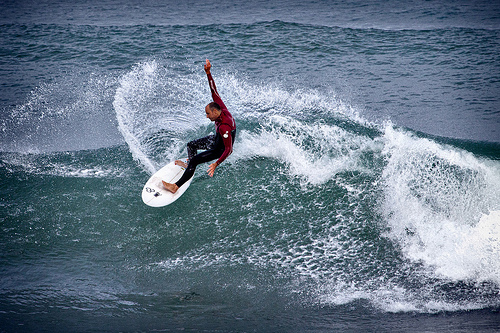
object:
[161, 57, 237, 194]
man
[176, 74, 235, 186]
wet suit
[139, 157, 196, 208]
surfboard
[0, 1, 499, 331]
ocean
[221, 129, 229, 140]
logo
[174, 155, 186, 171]
foot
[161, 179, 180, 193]
foot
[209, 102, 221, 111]
hair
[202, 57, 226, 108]
arm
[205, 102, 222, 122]
head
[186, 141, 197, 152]
knee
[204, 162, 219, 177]
hand